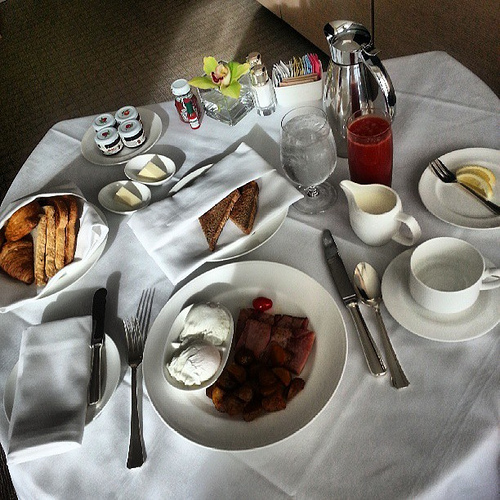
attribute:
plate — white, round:
[131, 254, 350, 452]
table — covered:
[0, 48, 500, 497]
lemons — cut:
[452, 162, 495, 196]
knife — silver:
[84, 286, 112, 406]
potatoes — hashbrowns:
[196, 340, 309, 417]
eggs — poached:
[167, 304, 232, 385]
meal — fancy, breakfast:
[0, 20, 497, 459]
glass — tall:
[347, 111, 397, 188]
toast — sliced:
[32, 196, 84, 288]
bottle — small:
[171, 74, 199, 122]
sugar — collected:
[270, 60, 292, 85]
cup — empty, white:
[409, 238, 499, 317]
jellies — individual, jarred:
[95, 107, 146, 158]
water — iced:
[283, 118, 338, 187]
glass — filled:
[281, 100, 340, 224]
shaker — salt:
[247, 74, 281, 117]